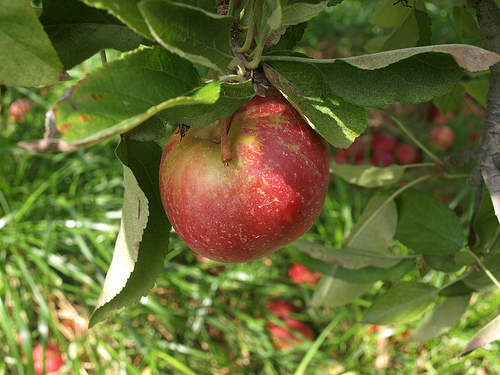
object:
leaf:
[33, 43, 252, 152]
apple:
[158, 91, 330, 265]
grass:
[0, 88, 382, 374]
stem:
[445, 0, 499, 219]